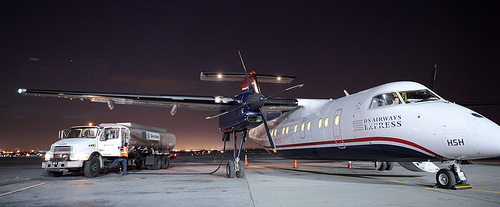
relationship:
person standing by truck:
[115, 141, 131, 170] [9, 82, 200, 197]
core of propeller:
[246, 91, 266, 108] [203, 48, 304, 152]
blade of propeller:
[198, 57, 298, 108] [199, 51, 299, 156]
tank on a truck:
[116, 116, 198, 157] [58, 114, 240, 182]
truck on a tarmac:
[40, 110, 177, 182] [14, 142, 492, 204]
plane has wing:
[17, 80, 499, 188] [16, 86, 336, 120]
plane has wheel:
[17, 80, 500, 188] [429, 157, 469, 195]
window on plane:
[334, 114, 339, 129] [17, 49, 497, 186]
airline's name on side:
[361, 112, 403, 130] [245, 79, 499, 188]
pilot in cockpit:
[391, 97, 400, 105] [358, 76, 452, 121]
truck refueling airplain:
[40, 122, 177, 178] [18, 49, 500, 191]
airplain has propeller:
[18, 49, 500, 191] [197, 49, 301, 150]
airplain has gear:
[18, 49, 500, 191] [433, 162, 465, 187]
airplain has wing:
[18, 49, 500, 191] [7, 70, 342, 148]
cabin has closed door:
[332, 78, 440, 134] [331, 109, 344, 136]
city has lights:
[167, 129, 238, 157] [2, 76, 239, 157]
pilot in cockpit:
[388, 94, 400, 108] [363, 85, 443, 110]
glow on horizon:
[171, 139, 256, 150] [1, 135, 267, 154]